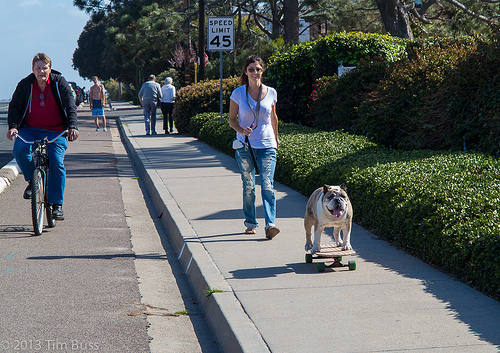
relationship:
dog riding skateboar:
[306, 182, 353, 254] [305, 243, 357, 273]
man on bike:
[6, 54, 79, 222] [12, 127, 57, 235]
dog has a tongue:
[306, 182, 353, 254] [334, 207, 344, 218]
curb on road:
[0, 99, 89, 195] [2, 96, 222, 353]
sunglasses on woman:
[244, 66, 266, 76] [228, 55, 280, 239]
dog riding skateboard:
[306, 182, 353, 254] [306, 237, 356, 270]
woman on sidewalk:
[228, 55, 280, 239] [108, 94, 498, 350]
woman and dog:
[228, 55, 280, 239] [306, 182, 353, 254]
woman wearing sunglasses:
[228, 55, 280, 239] [244, 66, 266, 76]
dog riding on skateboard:
[306, 182, 353, 254] [306, 237, 356, 270]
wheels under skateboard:
[305, 243, 357, 273] [306, 237, 356, 270]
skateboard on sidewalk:
[306, 237, 356, 270] [108, 94, 498, 350]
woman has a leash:
[228, 55, 280, 239] [244, 78, 264, 177]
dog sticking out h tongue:
[306, 182, 353, 254] [334, 207, 344, 218]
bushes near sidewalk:
[173, 30, 499, 297] [108, 94, 498, 350]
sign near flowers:
[204, 53, 210, 67] [168, 44, 198, 67]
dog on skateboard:
[306, 182, 353, 254] [306, 237, 356, 270]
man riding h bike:
[6, 54, 79, 222] [12, 127, 57, 235]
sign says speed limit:
[207, 16, 236, 52] [209, 18, 232, 36]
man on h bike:
[6, 54, 79, 222] [12, 127, 57, 235]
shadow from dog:
[226, 261, 349, 279] [306, 182, 353, 254]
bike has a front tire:
[12, 127, 57, 235] [33, 171, 48, 236]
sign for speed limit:
[207, 16, 236, 52] [209, 18, 232, 36]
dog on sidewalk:
[306, 182, 353, 254] [108, 94, 498, 350]